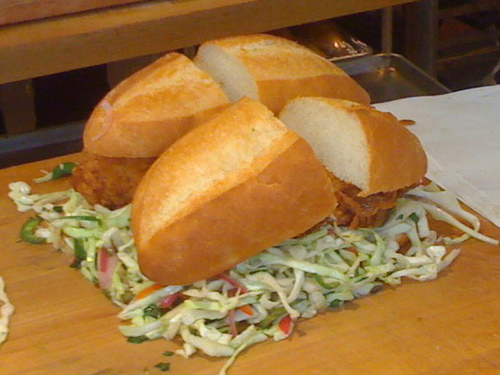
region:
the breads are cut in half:
[131, 34, 426, 274]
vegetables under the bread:
[37, 175, 330, 356]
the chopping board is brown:
[43, 280, 119, 367]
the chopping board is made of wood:
[38, 273, 109, 363]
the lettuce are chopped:
[123, 283, 255, 355]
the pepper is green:
[10, 213, 42, 251]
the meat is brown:
[73, 163, 143, 207]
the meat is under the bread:
[69, 150, 152, 213]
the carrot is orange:
[234, 298, 254, 317]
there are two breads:
[83, 35, 442, 314]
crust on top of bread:
[184, 184, 241, 203]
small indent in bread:
[270, 172, 298, 190]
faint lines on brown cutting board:
[40, 316, 82, 353]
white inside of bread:
[301, 109, 334, 134]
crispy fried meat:
[340, 183, 390, 219]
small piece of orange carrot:
[140, 286, 172, 306]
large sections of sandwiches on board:
[78, 44, 480, 280]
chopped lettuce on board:
[260, 256, 365, 302]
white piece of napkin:
[444, 108, 496, 175]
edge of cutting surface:
[22, 151, 77, 185]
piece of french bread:
[92, 78, 326, 300]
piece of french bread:
[279, 93, 451, 204]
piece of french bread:
[75, 38, 234, 172]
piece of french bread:
[195, 20, 377, 115]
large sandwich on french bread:
[123, 76, 449, 328]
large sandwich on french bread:
[61, 17, 378, 192]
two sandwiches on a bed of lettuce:
[0, 7, 462, 355]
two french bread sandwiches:
[52, 18, 445, 323]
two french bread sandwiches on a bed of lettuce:
[36, 13, 462, 321]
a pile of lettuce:
[207, 220, 436, 360]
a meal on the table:
[37, 55, 440, 356]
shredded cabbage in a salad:
[190, 283, 351, 337]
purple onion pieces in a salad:
[99, 248, 120, 292]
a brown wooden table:
[354, 329, 454, 371]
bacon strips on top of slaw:
[349, 194, 391, 228]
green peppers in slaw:
[23, 216, 109, 238]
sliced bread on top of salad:
[234, 90, 389, 210]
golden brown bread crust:
[209, 143, 268, 185]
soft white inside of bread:
[316, 124, 345, 149]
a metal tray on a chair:
[374, 56, 451, 93]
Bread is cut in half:
[118, 86, 439, 310]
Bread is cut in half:
[67, 31, 379, 170]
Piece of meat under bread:
[70, 141, 150, 211]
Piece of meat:
[316, 170, 401, 227]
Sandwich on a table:
[0, 26, 499, 373]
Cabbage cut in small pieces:
[12, 160, 482, 368]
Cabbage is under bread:
[0, 187, 485, 365]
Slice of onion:
[86, 239, 118, 298]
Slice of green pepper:
[16, 211, 46, 253]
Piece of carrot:
[273, 311, 298, 339]